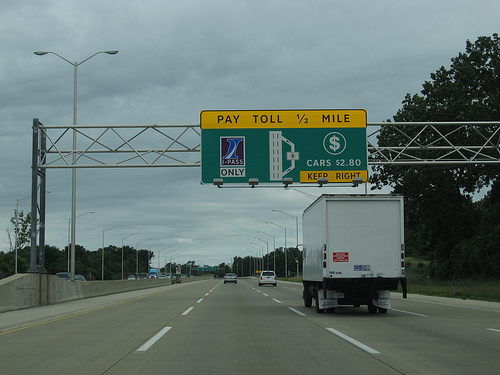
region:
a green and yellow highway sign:
[195, 107, 372, 186]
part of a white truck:
[302, 195, 409, 307]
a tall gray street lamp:
[31, 43, 118, 275]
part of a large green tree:
[353, 25, 498, 192]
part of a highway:
[0, 261, 498, 372]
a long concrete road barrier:
[3, 263, 170, 311]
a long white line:
[322, 319, 379, 357]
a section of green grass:
[407, 284, 494, 303]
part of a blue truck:
[147, 265, 159, 281]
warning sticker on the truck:
[329, 250, 357, 269]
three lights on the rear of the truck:
[398, 239, 406, 270]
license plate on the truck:
[329, 290, 346, 297]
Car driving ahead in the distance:
[221, 262, 241, 287]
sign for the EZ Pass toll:
[213, 125, 253, 183]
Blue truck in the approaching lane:
[143, 264, 162, 280]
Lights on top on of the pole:
[35, 46, 121, 61]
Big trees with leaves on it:
[407, 85, 499, 217]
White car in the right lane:
[249, 259, 289, 289]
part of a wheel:
[351, 273, 355, 283]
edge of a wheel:
[327, 293, 328, 300]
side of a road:
[261, 342, 263, 347]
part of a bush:
[419, 210, 429, 221]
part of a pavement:
[481, 195, 495, 223]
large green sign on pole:
[215, 88, 364, 197]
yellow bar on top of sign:
[194, 105, 362, 126]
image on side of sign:
[218, 125, 244, 177]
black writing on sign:
[215, 167, 243, 176]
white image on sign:
[255, 124, 302, 178]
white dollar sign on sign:
[325, 135, 343, 150]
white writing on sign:
[306, 154, 358, 169]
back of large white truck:
[327, 191, 403, 282]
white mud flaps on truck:
[315, 285, 343, 310]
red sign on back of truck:
[335, 250, 349, 264]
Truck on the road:
[299, 185, 414, 318]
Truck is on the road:
[299, 187, 414, 317]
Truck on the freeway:
[297, 188, 409, 318]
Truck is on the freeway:
[290, 185, 405, 320]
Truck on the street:
[295, 190, 408, 318]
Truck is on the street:
[295, 185, 415, 321]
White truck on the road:
[298, 186, 410, 316]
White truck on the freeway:
[293, 183, 412, 320]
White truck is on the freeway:
[299, 186, 408, 319]